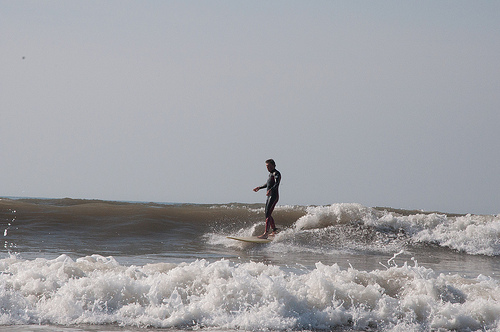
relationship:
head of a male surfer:
[259, 153, 285, 175] [252, 159, 283, 236]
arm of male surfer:
[253, 177, 269, 193] [252, 159, 283, 236]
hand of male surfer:
[250, 185, 261, 196] [252, 159, 283, 236]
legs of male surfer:
[257, 193, 285, 238] [252, 159, 283, 236]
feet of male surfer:
[252, 226, 286, 242] [252, 159, 283, 236]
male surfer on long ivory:
[252, 159, 283, 236] [231, 228, 278, 244]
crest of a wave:
[302, 207, 351, 234] [297, 197, 358, 232]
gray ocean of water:
[85, 206, 178, 236] [165, 225, 226, 283]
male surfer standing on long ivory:
[252, 159, 283, 236] [231, 228, 278, 244]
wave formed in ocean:
[297, 197, 358, 232] [98, 219, 157, 261]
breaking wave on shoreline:
[293, 209, 363, 245] [294, 195, 386, 245]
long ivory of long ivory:
[231, 228, 261, 258] [231, 228, 278, 244]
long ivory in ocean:
[231, 228, 278, 244] [98, 219, 157, 261]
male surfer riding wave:
[252, 159, 283, 236] [297, 197, 358, 232]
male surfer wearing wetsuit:
[252, 159, 283, 236] [259, 176, 282, 226]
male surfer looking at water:
[252, 159, 283, 236] [165, 225, 226, 283]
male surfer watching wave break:
[252, 159, 283, 236] [179, 207, 247, 254]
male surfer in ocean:
[252, 159, 283, 236] [98, 219, 157, 261]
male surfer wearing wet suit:
[252, 159, 283, 236] [253, 174, 281, 212]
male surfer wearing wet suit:
[252, 152, 303, 251] [253, 174, 281, 212]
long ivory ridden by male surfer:
[231, 228, 278, 244] [252, 152, 303, 251]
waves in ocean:
[294, 195, 386, 245] [98, 219, 157, 261]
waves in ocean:
[318, 205, 367, 284] [98, 219, 157, 261]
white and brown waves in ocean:
[118, 214, 193, 256] [98, 219, 157, 261]